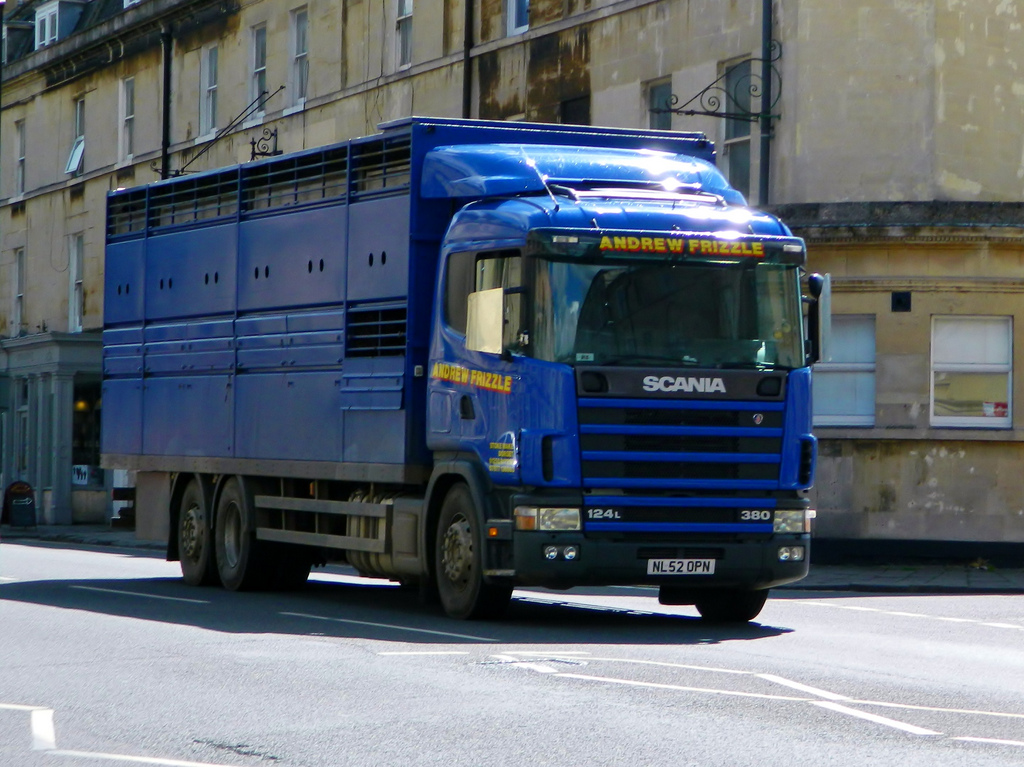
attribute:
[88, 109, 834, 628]
blue truck — large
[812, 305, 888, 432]
white window —   white,  building's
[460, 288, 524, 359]
mirror — side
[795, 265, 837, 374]
mirror — side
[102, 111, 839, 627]
truck — large, blue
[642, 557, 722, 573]
license plate — white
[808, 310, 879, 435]
window — glass